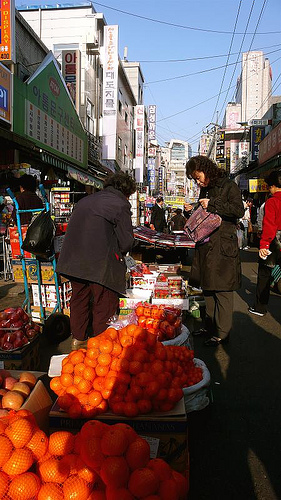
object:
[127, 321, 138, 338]
oranges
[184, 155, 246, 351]
woman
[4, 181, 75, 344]
cart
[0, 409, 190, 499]
bag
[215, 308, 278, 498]
shadow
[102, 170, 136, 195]
head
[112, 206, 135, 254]
arm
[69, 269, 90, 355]
leg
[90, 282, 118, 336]
leg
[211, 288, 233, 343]
leg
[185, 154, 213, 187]
head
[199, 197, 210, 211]
hand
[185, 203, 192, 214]
hand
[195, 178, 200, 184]
nose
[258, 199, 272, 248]
arm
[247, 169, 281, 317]
person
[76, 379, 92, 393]
orange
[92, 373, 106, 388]
orange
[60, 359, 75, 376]
orange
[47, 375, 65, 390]
orange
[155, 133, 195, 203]
building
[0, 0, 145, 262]
building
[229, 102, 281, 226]
building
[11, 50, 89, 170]
sign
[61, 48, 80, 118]
sign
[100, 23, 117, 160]
sign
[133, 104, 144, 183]
sign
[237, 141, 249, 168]
sign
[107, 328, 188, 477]
shadow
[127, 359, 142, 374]
orange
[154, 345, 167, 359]
orange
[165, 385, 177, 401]
orange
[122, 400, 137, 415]
orange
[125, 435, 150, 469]
orange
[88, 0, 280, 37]
wire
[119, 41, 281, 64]
wire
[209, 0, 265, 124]
wire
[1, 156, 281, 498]
market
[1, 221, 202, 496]
food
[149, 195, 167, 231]
person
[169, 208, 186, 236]
person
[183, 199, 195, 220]
person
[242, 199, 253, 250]
person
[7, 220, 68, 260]
box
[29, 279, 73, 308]
box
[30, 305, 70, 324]
box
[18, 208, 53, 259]
bag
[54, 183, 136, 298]
coat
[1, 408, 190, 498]
bundle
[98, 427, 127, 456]
orange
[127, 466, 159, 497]
orange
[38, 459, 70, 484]
orange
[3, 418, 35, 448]
orange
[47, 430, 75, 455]
orange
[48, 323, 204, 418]
bundle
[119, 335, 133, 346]
orange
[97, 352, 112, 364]
orange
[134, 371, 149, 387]
orange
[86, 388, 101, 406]
orange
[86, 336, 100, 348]
orange